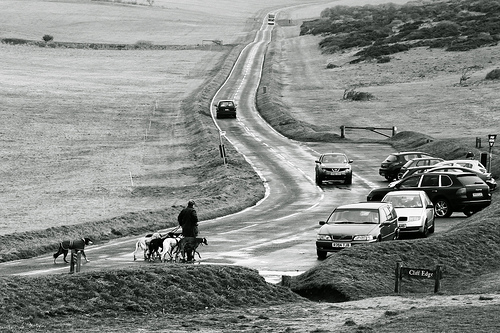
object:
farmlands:
[0, 0, 309, 235]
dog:
[51, 234, 94, 265]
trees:
[343, 86, 372, 104]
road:
[1, 3, 473, 284]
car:
[212, 98, 238, 120]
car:
[314, 203, 399, 260]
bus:
[264, 13, 275, 25]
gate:
[338, 124, 396, 140]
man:
[175, 198, 198, 263]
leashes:
[165, 224, 180, 236]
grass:
[0, 0, 315, 233]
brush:
[297, 0, 500, 66]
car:
[313, 151, 356, 186]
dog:
[174, 236, 208, 262]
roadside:
[256, 4, 500, 303]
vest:
[60, 237, 87, 253]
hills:
[253, 0, 500, 144]